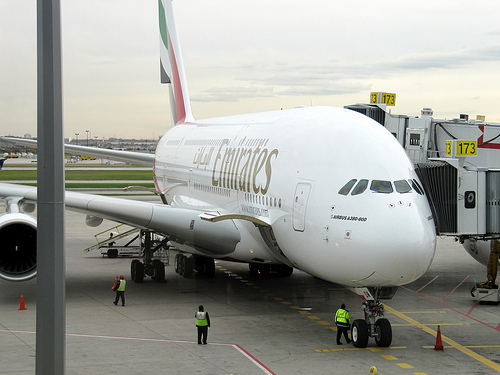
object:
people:
[191, 305, 212, 343]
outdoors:
[0, 0, 500, 375]